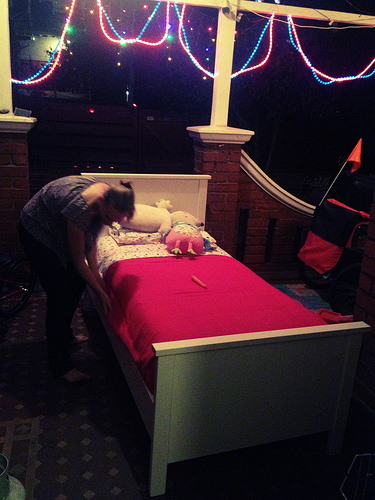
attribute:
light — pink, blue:
[98, 13, 132, 49]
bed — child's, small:
[84, 173, 352, 457]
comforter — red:
[118, 255, 277, 331]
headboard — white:
[87, 175, 211, 217]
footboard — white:
[164, 347, 348, 437]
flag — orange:
[350, 142, 360, 172]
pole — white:
[321, 162, 346, 200]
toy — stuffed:
[162, 212, 209, 255]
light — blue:
[261, 27, 274, 64]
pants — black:
[22, 237, 93, 369]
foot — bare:
[65, 370, 83, 382]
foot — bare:
[74, 334, 90, 346]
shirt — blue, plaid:
[28, 181, 85, 242]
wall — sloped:
[241, 188, 303, 278]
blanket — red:
[301, 201, 356, 276]